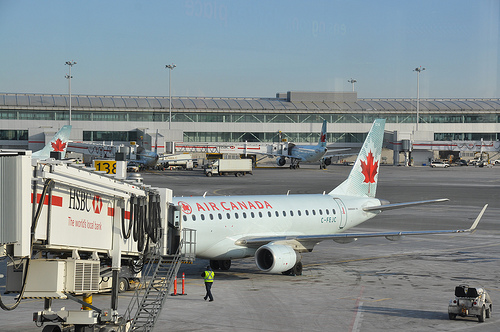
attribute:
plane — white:
[170, 126, 400, 280]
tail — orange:
[343, 120, 388, 212]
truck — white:
[193, 148, 252, 176]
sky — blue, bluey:
[219, 29, 241, 56]